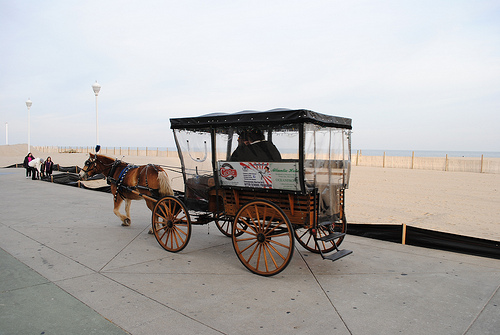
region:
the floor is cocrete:
[102, 264, 269, 305]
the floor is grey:
[88, 247, 222, 319]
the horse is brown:
[73, 140, 168, 223]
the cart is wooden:
[161, 110, 345, 280]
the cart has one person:
[167, 116, 345, 267]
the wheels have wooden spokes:
[216, 201, 301, 280]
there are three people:
[17, 135, 59, 180]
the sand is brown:
[387, 172, 467, 220]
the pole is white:
[82, 73, 105, 157]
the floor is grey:
[8, 284, 59, 333]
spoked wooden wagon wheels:
[148, 193, 294, 278]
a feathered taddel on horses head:
[93, 138, 104, 156]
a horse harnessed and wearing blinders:
[77, 154, 171, 236]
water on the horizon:
[285, 137, 498, 161]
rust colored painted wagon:
[210, 184, 328, 226]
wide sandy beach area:
[333, 179, 498, 234]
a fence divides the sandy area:
[359, 146, 499, 173]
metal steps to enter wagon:
[310, 191, 355, 270]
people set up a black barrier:
[11, 150, 75, 187]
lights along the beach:
[13, 72, 105, 159]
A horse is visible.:
[40, 125, 288, 312]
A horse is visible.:
[80, 140, 217, 322]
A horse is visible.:
[130, 151, 181, 239]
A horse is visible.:
[117, 120, 132, 160]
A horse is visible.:
[55, 147, 140, 262]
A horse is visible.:
[97, 125, 181, 259]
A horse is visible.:
[102, 178, 196, 293]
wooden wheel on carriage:
[150, 196, 192, 253]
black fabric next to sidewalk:
[347, 221, 498, 263]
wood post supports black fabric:
[400, 223, 407, 244]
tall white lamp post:
[91, 78, 101, 149]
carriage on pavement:
[0, 165, 499, 334]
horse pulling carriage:
[75, 151, 175, 237]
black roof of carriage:
[167, 106, 352, 135]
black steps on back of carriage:
[318, 225, 353, 262]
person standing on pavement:
[44, 156, 54, 181]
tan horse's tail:
[157, 169, 172, 196]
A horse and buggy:
[62, 90, 374, 279]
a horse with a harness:
[58, 149, 178, 246]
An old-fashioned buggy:
[146, 90, 379, 291]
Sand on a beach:
[401, 175, 471, 220]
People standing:
[23, 152, 54, 187]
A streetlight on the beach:
[77, 65, 119, 157]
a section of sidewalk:
[40, 200, 110, 272]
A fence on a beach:
[367, 137, 495, 188]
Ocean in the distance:
[370, 142, 495, 163]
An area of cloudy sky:
[271, 31, 432, 92]